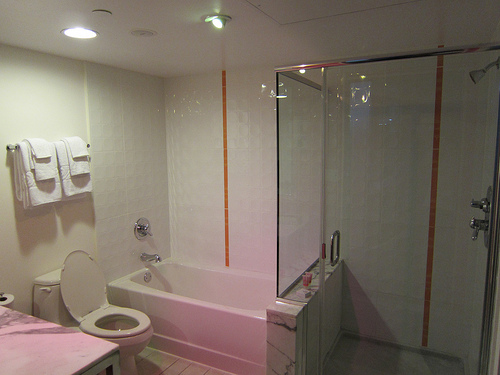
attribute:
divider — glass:
[274, 69, 326, 299]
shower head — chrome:
[465, 54, 499, 86]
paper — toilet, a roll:
[4, 285, 20, 333]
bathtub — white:
[125, 236, 297, 358]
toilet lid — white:
[56, 246, 107, 322]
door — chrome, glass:
[317, 48, 462, 374]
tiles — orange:
[216, 72, 237, 272]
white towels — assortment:
[6, 134, 101, 213]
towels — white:
[12, 135, 92, 209]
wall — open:
[181, 71, 475, 331]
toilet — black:
[59, 251, 151, 371]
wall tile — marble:
[264, 304, 299, 373]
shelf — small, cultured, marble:
[264, 255, 339, 317]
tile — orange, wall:
[223, 245, 230, 269]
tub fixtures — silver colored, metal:
[132, 214, 165, 266]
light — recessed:
[60, 27, 99, 39]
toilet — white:
[46, 232, 175, 342]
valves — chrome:
[468, 186, 498, 253]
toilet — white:
[34, 249, 153, 354]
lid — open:
[58, 248, 112, 323]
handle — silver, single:
[133, 217, 154, 241]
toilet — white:
[52, 258, 156, 350]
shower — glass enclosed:
[272, 70, 499, 370]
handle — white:
[33, 283, 51, 295]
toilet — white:
[33, 249, 151, 373]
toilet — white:
[24, 245, 155, 373]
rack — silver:
[7, 126, 78, 169]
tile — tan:
[329, 334, 361, 364]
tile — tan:
[348, 339, 400, 373]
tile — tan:
[133, 348, 178, 373]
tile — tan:
[135, 346, 155, 359]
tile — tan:
[156, 356, 188, 372]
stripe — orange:
[220, 69, 230, 266]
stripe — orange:
[418, 41, 446, 349]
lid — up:
[59, 245, 111, 314]